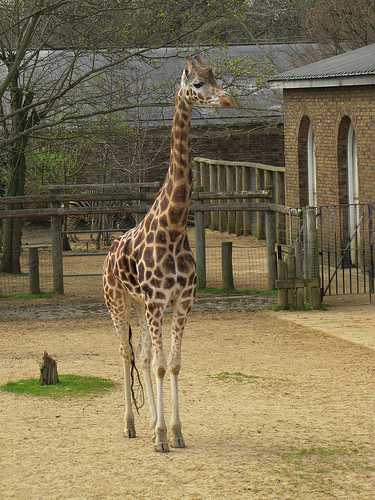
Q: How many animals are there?
A: 1.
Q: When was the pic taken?
A: During the day.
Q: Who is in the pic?
A: Giraffe.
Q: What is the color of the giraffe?
A: Brown and white.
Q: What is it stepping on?
A: Sand.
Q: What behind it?
A: Fence.